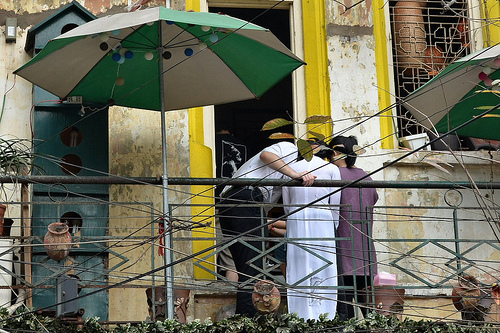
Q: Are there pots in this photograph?
A: Yes, there is a pot.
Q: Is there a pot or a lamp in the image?
A: Yes, there is a pot.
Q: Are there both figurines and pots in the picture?
A: No, there is a pot but no figurines.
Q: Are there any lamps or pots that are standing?
A: Yes, the pot is standing.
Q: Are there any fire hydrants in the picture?
A: No, there are no fire hydrants.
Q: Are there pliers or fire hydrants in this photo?
A: No, there are no fire hydrants or pliers.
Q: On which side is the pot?
A: The pot is on the left of the image.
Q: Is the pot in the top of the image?
A: No, the pot is in the bottom of the image.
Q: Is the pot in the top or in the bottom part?
A: The pot is in the bottom of the image.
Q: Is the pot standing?
A: Yes, the pot is standing.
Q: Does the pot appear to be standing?
A: Yes, the pot is standing.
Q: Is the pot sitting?
A: No, the pot is standing.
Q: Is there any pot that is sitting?
A: No, there is a pot but it is standing.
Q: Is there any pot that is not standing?
A: No, there is a pot but it is standing.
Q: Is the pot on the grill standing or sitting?
A: The pot is standing.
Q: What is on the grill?
A: The pot is on the grill.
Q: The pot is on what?
A: The pot is on the grill.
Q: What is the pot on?
A: The pot is on the grill.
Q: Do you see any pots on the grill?
A: Yes, there is a pot on the grill.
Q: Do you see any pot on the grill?
A: Yes, there is a pot on the grill.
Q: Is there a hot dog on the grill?
A: No, there is a pot on the grill.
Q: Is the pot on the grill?
A: Yes, the pot is on the grill.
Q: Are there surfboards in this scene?
A: No, there are no surfboards.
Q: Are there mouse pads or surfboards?
A: No, there are no surfboards or mouse pads.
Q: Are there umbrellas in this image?
A: Yes, there are umbrellas.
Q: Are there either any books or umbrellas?
A: Yes, there are umbrellas.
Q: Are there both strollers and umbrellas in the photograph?
A: No, there are umbrellas but no strollers.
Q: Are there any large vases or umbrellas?
A: Yes, there are large umbrellas.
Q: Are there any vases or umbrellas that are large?
A: Yes, the umbrellas are large.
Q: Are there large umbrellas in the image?
A: Yes, there are large umbrellas.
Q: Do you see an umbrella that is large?
A: Yes, there are umbrellas that are large.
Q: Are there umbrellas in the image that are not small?
A: Yes, there are large umbrellas.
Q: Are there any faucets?
A: No, there are no faucets.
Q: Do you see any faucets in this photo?
A: No, there are no faucets.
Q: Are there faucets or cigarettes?
A: No, there are no faucets or cigarettes.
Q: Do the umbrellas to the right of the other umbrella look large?
A: Yes, the umbrellas are large.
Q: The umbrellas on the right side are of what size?
A: The umbrellas are large.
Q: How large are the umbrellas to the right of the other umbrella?
A: The umbrellas are large.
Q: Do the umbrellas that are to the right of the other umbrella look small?
A: No, the umbrellas are large.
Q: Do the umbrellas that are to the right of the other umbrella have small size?
A: No, the umbrellas are large.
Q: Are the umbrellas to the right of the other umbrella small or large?
A: The umbrellas are large.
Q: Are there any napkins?
A: No, there are no napkins.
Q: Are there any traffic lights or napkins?
A: No, there are no napkins or traffic lights.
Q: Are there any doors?
A: Yes, there is a door.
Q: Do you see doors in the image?
A: Yes, there is a door.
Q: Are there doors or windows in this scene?
A: Yes, there is a door.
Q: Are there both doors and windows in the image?
A: Yes, there are both a door and a window.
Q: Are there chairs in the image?
A: No, there are no chairs.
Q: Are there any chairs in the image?
A: No, there are no chairs.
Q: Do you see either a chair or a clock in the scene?
A: No, there are no chairs or clocks.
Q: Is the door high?
A: Yes, the door is high.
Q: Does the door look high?
A: Yes, the door is high.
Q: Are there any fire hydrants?
A: No, there are no fire hydrants.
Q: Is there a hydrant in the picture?
A: No, there are no fire hydrants.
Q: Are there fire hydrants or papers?
A: No, there are no fire hydrants or papers.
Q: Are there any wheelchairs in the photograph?
A: No, there are no wheelchairs.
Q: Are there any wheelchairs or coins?
A: No, there are no wheelchairs or coins.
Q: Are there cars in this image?
A: No, there are no cars.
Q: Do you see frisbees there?
A: No, there are no frisbees.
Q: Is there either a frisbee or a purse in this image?
A: No, there are no frisbees or purses.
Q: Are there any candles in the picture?
A: No, there are no candles.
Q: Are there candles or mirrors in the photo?
A: No, there are no candles or mirrors.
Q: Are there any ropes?
A: No, there are no ropes.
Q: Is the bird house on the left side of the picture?
A: Yes, the bird house is on the left of the image.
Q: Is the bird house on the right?
A: No, the bird house is on the left of the image.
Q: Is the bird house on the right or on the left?
A: The bird house is on the left of the image.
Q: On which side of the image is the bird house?
A: The bird house is on the left of the image.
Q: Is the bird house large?
A: Yes, the bird house is large.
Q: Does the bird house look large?
A: Yes, the bird house is large.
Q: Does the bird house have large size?
A: Yes, the bird house is large.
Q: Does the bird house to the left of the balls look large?
A: Yes, the bird house is large.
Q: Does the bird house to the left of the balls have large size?
A: Yes, the bird house is large.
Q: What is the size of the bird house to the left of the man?
A: The bird house is large.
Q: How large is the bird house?
A: The bird house is large.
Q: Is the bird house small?
A: No, the bird house is large.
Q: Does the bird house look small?
A: No, the bird house is large.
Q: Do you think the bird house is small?
A: No, the bird house is large.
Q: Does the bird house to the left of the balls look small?
A: No, the bird house is large.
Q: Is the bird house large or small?
A: The bird house is large.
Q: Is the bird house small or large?
A: The bird house is large.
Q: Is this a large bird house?
A: Yes, this is a large bird house.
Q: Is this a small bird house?
A: No, this is a large bird house.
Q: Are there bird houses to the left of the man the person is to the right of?
A: Yes, there is a bird house to the left of the man.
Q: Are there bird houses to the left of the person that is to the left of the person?
A: Yes, there is a bird house to the left of the man.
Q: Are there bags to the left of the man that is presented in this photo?
A: No, there is a bird house to the left of the man.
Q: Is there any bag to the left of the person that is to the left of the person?
A: No, there is a bird house to the left of the man.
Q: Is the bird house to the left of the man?
A: Yes, the bird house is to the left of the man.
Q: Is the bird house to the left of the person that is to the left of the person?
A: Yes, the bird house is to the left of the man.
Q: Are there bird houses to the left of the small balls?
A: Yes, there is a bird house to the left of the balls.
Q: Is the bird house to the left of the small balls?
A: Yes, the bird house is to the left of the balls.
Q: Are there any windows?
A: Yes, there is a window.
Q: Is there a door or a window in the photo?
A: Yes, there is a window.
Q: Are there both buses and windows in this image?
A: No, there is a window but no buses.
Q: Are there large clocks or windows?
A: Yes, there is a large window.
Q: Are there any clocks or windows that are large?
A: Yes, the window is large.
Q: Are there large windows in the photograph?
A: Yes, there is a large window.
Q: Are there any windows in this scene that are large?
A: Yes, there is a window that is large.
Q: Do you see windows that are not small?
A: Yes, there is a large window.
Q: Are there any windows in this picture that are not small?
A: Yes, there is a large window.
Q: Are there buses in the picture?
A: No, there are no buses.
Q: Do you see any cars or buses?
A: No, there are no buses or cars.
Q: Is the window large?
A: Yes, the window is large.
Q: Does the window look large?
A: Yes, the window is large.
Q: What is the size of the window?
A: The window is large.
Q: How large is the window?
A: The window is large.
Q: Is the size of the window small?
A: No, the window is large.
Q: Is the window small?
A: No, the window is large.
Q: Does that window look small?
A: No, the window is large.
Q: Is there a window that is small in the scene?
A: No, there is a window but it is large.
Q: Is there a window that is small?
A: No, there is a window but it is large.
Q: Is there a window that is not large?
A: No, there is a window but it is large.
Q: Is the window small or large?
A: The window is large.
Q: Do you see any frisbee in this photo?
A: No, there are no frisbees.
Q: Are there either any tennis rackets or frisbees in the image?
A: No, there are no frisbees or tennis rackets.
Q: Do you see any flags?
A: No, there are no flags.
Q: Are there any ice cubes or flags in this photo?
A: No, there are no flags or ice cubes.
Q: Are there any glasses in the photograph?
A: No, there are no glasses.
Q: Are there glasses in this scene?
A: No, there are no glasses.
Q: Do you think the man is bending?
A: Yes, the man is bending.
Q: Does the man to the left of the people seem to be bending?
A: Yes, the man is bending.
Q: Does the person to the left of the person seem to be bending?
A: Yes, the man is bending.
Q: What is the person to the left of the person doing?
A: The man is bending.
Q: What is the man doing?
A: The man is bending.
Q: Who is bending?
A: The man is bending.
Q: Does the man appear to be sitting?
A: No, the man is bending.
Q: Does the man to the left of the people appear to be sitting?
A: No, the man is bending.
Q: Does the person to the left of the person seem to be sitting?
A: No, the man is bending.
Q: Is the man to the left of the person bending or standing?
A: The man is bending.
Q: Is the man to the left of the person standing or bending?
A: The man is bending.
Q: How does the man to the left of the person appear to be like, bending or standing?
A: The man is bending.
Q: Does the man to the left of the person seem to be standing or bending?
A: The man is bending.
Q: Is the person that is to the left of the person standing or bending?
A: The man is bending.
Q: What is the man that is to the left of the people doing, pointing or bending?
A: The man is bending.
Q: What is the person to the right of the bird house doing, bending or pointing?
A: The man is bending.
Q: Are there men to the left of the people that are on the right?
A: Yes, there is a man to the left of the people.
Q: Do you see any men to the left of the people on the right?
A: Yes, there is a man to the left of the people.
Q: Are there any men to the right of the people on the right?
A: No, the man is to the left of the people.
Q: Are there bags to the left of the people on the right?
A: No, there is a man to the left of the people.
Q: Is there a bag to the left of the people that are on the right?
A: No, there is a man to the left of the people.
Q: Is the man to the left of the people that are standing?
A: Yes, the man is to the left of the people.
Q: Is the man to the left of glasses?
A: No, the man is to the left of the people.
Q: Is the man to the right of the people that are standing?
A: No, the man is to the left of the people.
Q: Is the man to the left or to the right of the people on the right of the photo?
A: The man is to the left of the people.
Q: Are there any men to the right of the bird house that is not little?
A: Yes, there is a man to the right of the bird house.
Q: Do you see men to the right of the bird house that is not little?
A: Yes, there is a man to the right of the bird house.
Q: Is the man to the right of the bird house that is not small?
A: Yes, the man is to the right of the bird house.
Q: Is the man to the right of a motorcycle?
A: No, the man is to the right of the bird house.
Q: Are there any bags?
A: No, there are no bags.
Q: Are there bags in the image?
A: No, there are no bags.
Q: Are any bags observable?
A: No, there are no bags.